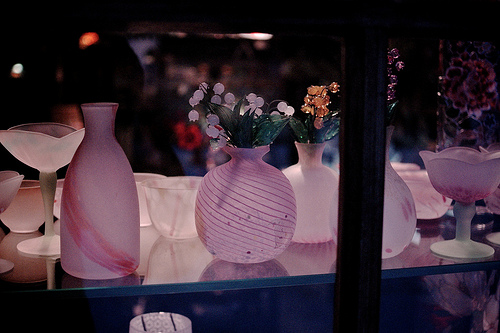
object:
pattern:
[224, 198, 289, 234]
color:
[61, 180, 140, 277]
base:
[427, 237, 497, 259]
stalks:
[297, 83, 339, 143]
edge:
[74, 278, 293, 301]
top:
[1, 224, 493, 294]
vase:
[2, 121, 85, 258]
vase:
[419, 147, 500, 260]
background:
[0, 5, 498, 133]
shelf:
[4, 250, 493, 299]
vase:
[279, 141, 344, 245]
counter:
[153, 250, 212, 284]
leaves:
[240, 117, 269, 142]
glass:
[2, 170, 20, 203]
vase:
[194, 145, 299, 264]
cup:
[142, 175, 200, 239]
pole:
[341, 103, 380, 273]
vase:
[328, 124, 418, 259]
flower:
[444, 60, 484, 113]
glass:
[440, 148, 484, 195]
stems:
[231, 116, 262, 139]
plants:
[187, 81, 297, 260]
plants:
[283, 81, 341, 157]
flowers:
[301, 82, 340, 130]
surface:
[170, 241, 215, 274]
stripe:
[69, 200, 102, 258]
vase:
[58, 102, 141, 280]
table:
[145, 235, 202, 281]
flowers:
[187, 82, 295, 152]